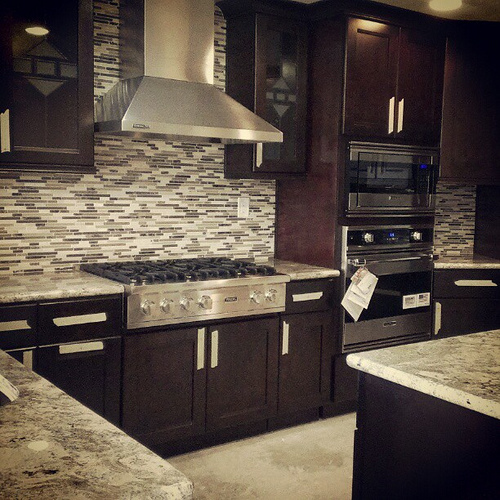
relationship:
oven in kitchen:
[340, 134, 435, 354] [3, 5, 493, 492]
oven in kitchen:
[72, 256, 289, 329] [67, 263, 412, 460]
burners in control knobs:
[94, 257, 281, 284] [132, 287, 287, 316]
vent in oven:
[95, 0, 282, 146] [72, 256, 289, 329]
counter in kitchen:
[2, 412, 159, 499] [3, 5, 493, 492]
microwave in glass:
[344, 140, 438, 215] [358, 153, 424, 208]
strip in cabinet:
[277, 317, 291, 355] [281, 307, 338, 418]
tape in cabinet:
[208, 325, 219, 369] [118, 313, 280, 436]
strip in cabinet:
[197, 328, 205, 370] [121, 317, 282, 459]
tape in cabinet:
[52, 313, 108, 326] [0, 290, 127, 442]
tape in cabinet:
[451, 276, 498, 288] [433, 265, 498, 341]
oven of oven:
[72, 256, 289, 329] [81, 256, 290, 458]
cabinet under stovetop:
[204, 316, 279, 433] [77, 255, 280, 285]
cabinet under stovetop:
[117, 322, 205, 445] [77, 255, 280, 285]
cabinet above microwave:
[309, 11, 446, 147] [344, 140, 438, 215]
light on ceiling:
[421, 2, 475, 25] [476, 4, 492, 22]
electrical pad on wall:
[236, 193, 251, 218] [16, 170, 215, 252]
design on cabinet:
[261, 25, 301, 160] [221, 0, 316, 180]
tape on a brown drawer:
[49, 310, 119, 329] [287, 279, 334, 312]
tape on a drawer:
[290, 290, 327, 301] [35, 294, 127, 328]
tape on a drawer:
[0, 321, 32, 331] [2, 290, 128, 352]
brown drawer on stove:
[287, 279, 334, 312] [96, 247, 348, 353]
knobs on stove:
[159, 298, 178, 317] [96, 247, 348, 353]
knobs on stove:
[180, 296, 197, 313] [96, 247, 348, 353]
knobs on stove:
[199, 294, 215, 310] [96, 247, 348, 353]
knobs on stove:
[249, 290, 264, 306] [96, 247, 348, 353]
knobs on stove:
[267, 290, 279, 303] [96, 247, 348, 353]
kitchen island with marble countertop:
[345, 327, 499, 498] [346, 330, 498, 407]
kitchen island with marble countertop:
[345, 327, 499, 498] [436, 252, 498, 272]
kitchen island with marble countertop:
[345, 327, 499, 498] [268, 252, 339, 281]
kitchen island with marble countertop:
[345, 327, 499, 498] [5, 272, 122, 292]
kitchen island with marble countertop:
[345, 327, 499, 498] [4, 370, 184, 498]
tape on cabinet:
[387, 95, 395, 135] [309, 11, 446, 147]